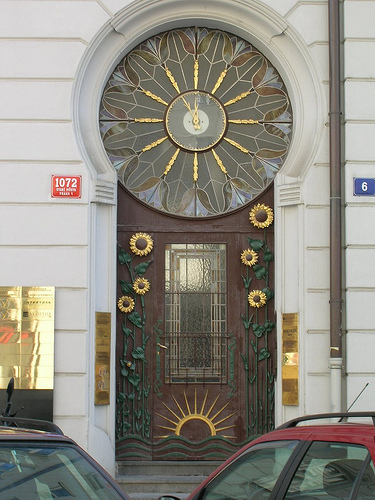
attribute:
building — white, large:
[2, 5, 373, 497]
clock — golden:
[100, 26, 291, 217]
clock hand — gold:
[181, 93, 195, 131]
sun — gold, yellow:
[135, 60, 260, 180]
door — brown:
[127, 224, 268, 463]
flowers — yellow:
[235, 244, 264, 324]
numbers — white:
[54, 178, 79, 189]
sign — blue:
[353, 176, 374, 195]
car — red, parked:
[158, 410, 373, 498]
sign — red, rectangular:
[51, 174, 80, 198]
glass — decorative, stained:
[162, 242, 231, 387]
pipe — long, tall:
[325, 4, 352, 424]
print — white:
[53, 178, 78, 197]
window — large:
[96, 26, 298, 221]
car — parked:
[2, 419, 138, 500]